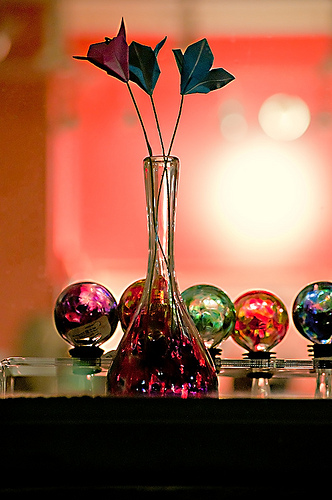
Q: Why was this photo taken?
A: To show the beauty of the ornaments.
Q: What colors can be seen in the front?
A: Pink, purple, red.